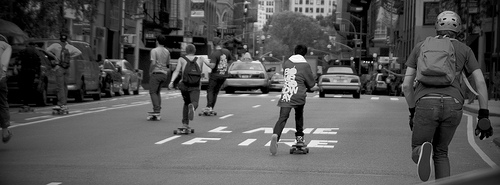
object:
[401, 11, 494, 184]
guy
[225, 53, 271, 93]
taxi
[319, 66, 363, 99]
car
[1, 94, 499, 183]
road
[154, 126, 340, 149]
fire lane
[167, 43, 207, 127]
girl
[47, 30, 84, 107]
man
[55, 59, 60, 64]
hands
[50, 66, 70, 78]
hips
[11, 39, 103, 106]
pickup truck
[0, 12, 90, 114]
side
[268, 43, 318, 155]
man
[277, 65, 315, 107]
jacket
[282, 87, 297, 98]
writing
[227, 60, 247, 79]
cab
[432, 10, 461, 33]
helmet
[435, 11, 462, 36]
head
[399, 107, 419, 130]
glove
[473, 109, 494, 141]
glove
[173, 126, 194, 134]
skateboard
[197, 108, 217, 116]
skateboard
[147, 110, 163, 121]
skateboard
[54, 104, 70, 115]
skateboard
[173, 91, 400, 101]
crosswalk lane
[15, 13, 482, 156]
view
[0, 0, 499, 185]
city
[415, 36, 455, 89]
backpack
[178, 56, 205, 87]
backpack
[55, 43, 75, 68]
backpack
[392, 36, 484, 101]
back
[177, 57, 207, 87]
back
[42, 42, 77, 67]
back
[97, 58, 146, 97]
van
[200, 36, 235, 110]
person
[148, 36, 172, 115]
person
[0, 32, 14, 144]
person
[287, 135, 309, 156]
roller skates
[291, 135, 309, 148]
foot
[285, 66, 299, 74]
symbol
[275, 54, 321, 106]
back